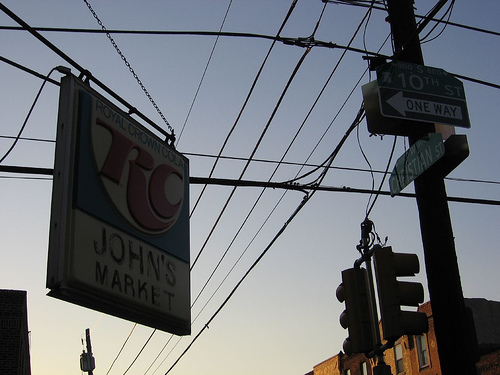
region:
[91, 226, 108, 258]
a letter is written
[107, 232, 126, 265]
a letter is written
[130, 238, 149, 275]
a letter is written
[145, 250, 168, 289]
a letter is written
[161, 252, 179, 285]
a letter is written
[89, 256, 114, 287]
a letter is written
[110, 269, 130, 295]
a letter is written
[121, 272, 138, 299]
a letter is written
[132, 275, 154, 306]
a letter is written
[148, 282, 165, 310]
a letter is written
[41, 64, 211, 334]
a business sign hanging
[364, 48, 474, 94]
a street sign on a pole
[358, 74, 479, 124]
"One way" sign on a pole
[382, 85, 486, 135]
a street sign with an arrow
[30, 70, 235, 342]
royal crown cola RC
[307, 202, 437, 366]
two traffic lights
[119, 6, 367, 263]
power lines running across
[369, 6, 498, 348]
a tall pole with signs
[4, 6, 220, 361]
a thin pole hanging a sign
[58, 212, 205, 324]
John's Market business sign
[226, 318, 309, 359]
A clear grey cloud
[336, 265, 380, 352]
Grey colored traffic lights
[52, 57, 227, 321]
A big market poster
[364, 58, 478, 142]
A tenth street poster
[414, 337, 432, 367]
A small grey window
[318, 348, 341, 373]
A brown brick wall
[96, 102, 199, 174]
ROYAL CROWN COLAR Poster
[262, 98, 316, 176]
Long black electricity lines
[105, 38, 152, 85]
Long stretch of wire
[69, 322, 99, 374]
A black electricity transformer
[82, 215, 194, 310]
John's Market on a sign.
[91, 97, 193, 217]
RC on a sign.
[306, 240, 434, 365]
Two hanging traffic lights.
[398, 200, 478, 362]
The pole is wooden.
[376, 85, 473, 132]
One way sign on the pole.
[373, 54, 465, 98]
10th street sign on the pole.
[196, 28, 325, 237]
Power lines in the air.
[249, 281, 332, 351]
The sky is blue.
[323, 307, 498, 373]
The building is brick.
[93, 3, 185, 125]
Chain on the sign.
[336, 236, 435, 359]
The back and side of two stop lights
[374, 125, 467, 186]
A green street sign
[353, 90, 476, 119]
A black with white arrow one way sign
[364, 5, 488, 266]
A utility pole with signs attached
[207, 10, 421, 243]
Wires running to a utility pole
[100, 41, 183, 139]
A chain helping to support a sign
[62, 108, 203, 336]
An RC Cola advertisement sign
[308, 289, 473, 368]
A brick building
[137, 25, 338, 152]
A blue grey sky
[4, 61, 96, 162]
A cord running to a sign